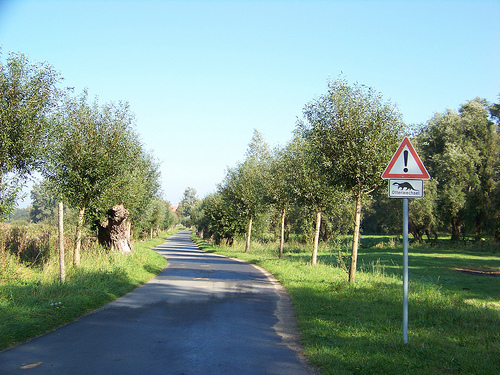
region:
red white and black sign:
[375, 135, 427, 183]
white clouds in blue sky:
[21, 9, 65, 37]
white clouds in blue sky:
[80, 25, 134, 105]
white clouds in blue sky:
[124, 11, 209, 46]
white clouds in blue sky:
[110, 43, 160, 87]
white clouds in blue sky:
[147, 62, 202, 116]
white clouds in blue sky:
[155, 92, 212, 152]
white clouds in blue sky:
[221, 53, 291, 107]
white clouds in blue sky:
[232, 25, 309, 90]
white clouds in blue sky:
[340, 12, 412, 56]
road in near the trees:
[18, 26, 468, 351]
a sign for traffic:
[358, 135, 450, 339]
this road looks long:
[119, 204, 285, 356]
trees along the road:
[202, 169, 364, 276]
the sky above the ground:
[104, 12, 271, 114]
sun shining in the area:
[147, 221, 474, 354]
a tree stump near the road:
[102, 203, 144, 267]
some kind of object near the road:
[439, 244, 498, 293]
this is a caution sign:
[373, 134, 432, 186]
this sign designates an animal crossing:
[352, 127, 434, 229]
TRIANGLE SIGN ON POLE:
[382, 129, 438, 344]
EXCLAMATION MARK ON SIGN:
[393, 144, 430, 188]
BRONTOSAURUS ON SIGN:
[393, 173, 430, 193]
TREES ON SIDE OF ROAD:
[235, 125, 384, 255]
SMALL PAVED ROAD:
[131, 197, 237, 367]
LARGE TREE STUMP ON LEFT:
[107, 207, 141, 235]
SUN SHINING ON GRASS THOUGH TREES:
[284, 207, 468, 334]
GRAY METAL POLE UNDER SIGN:
[399, 190, 426, 347]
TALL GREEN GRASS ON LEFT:
[12, 211, 68, 290]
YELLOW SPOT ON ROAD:
[14, 346, 61, 371]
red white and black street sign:
[391, 146, 426, 206]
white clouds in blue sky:
[14, 9, 56, 50]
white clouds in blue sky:
[52, 21, 104, 83]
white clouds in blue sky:
[141, 31, 209, 76]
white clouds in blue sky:
[394, 26, 439, 91]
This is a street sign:
[343, 91, 478, 315]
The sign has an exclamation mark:
[366, 134, 442, 166]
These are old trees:
[198, 84, 381, 314]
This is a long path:
[140, 241, 207, 371]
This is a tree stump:
[50, 181, 159, 253]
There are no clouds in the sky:
[155, 71, 307, 166]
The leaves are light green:
[283, 132, 400, 180]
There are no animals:
[95, 226, 262, 373]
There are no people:
[158, 214, 274, 340]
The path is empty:
[225, 245, 312, 371]